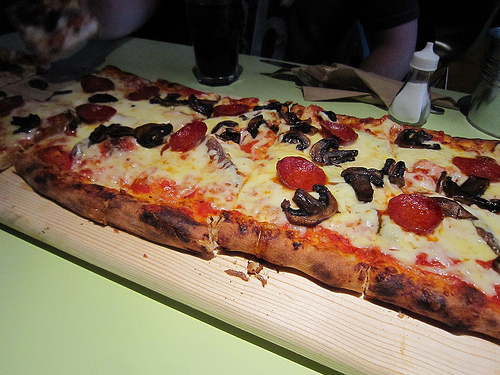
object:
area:
[142, 205, 208, 241]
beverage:
[192, 17, 236, 76]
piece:
[0, 164, 500, 375]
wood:
[0, 161, 500, 375]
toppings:
[16, 72, 498, 320]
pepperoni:
[276, 156, 325, 192]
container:
[389, 42, 439, 127]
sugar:
[389, 83, 429, 124]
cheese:
[0, 77, 499, 298]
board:
[0, 166, 500, 375]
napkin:
[290, 65, 459, 109]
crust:
[13, 152, 500, 339]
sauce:
[150, 196, 385, 285]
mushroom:
[282, 184, 337, 226]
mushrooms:
[309, 136, 405, 203]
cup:
[191, 26, 243, 87]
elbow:
[97, 5, 144, 37]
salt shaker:
[384, 41, 440, 128]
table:
[0, 38, 500, 375]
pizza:
[0, 63, 500, 340]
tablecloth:
[0, 228, 334, 375]